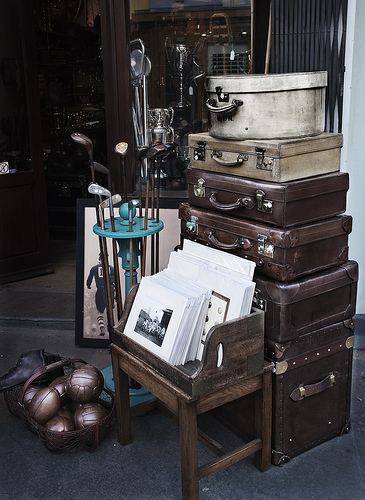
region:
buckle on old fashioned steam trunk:
[288, 376, 346, 400]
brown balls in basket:
[61, 364, 101, 402]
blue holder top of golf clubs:
[78, 204, 167, 242]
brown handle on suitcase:
[192, 185, 268, 207]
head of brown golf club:
[70, 129, 96, 153]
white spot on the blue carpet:
[202, 483, 219, 489]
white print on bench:
[115, 272, 207, 367]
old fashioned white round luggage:
[183, 56, 336, 139]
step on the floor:
[11, 278, 74, 309]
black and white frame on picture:
[62, 188, 196, 361]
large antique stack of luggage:
[181, 68, 359, 430]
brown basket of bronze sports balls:
[12, 370, 118, 453]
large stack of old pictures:
[110, 255, 267, 378]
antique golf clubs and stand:
[68, 130, 171, 414]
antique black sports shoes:
[0, 347, 67, 385]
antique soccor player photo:
[73, 194, 139, 357]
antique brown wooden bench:
[104, 341, 279, 496]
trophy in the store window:
[154, 34, 200, 109]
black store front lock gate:
[279, 1, 355, 135]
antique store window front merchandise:
[102, 3, 351, 188]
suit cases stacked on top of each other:
[256, 129, 358, 331]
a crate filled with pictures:
[119, 241, 271, 383]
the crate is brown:
[105, 273, 261, 395]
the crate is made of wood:
[95, 258, 275, 402]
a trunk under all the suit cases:
[257, 110, 358, 472]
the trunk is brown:
[266, 317, 345, 471]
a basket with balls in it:
[18, 352, 113, 463]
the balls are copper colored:
[20, 358, 115, 439]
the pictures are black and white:
[128, 280, 186, 376]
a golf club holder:
[67, 35, 170, 266]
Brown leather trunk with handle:
[274, 336, 352, 465]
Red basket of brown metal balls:
[19, 354, 119, 454]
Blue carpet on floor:
[7, 408, 362, 493]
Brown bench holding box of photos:
[107, 341, 273, 496]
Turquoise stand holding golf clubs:
[92, 201, 162, 406]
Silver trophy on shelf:
[144, 105, 175, 178]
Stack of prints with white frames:
[122, 236, 257, 368]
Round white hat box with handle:
[207, 74, 325, 139]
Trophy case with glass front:
[126, 4, 252, 199]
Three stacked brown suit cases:
[179, 167, 359, 341]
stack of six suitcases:
[179, 75, 355, 469]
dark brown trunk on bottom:
[215, 339, 355, 468]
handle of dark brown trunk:
[287, 369, 339, 403]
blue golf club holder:
[73, 133, 156, 401]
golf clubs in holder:
[69, 129, 171, 392]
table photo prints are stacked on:
[106, 280, 277, 487]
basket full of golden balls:
[7, 345, 113, 451]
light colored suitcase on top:
[205, 63, 328, 133]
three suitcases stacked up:
[183, 132, 350, 271]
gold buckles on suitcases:
[180, 139, 272, 256]